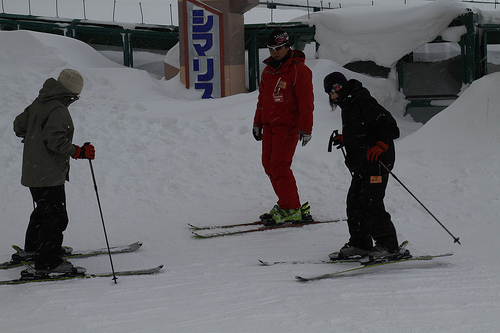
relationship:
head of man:
[267, 26, 302, 72] [249, 25, 316, 228]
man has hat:
[227, 13, 332, 183] [260, 12, 292, 43]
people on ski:
[2, 19, 427, 283] [68, 222, 163, 296]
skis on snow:
[257, 252, 456, 282] [36, 71, 478, 324]